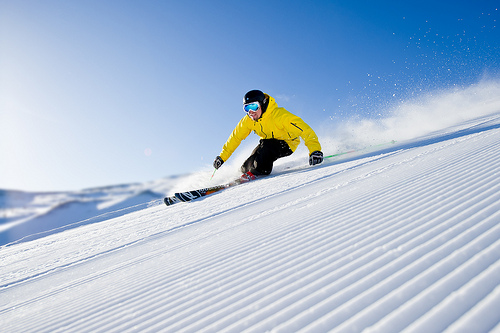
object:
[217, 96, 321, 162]
jacket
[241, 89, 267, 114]
helmet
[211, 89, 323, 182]
guy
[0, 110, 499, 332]
ground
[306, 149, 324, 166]
gloves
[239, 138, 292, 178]
pants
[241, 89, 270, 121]
head